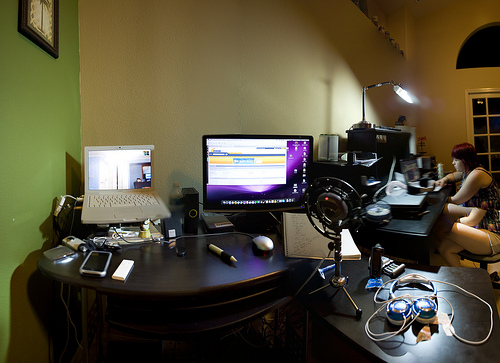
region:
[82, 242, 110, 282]
cellphone on the table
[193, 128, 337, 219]
monitor on the table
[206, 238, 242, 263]
pen on the table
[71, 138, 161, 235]
laptop on the table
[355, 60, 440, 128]
overhead light on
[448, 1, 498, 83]
half moon window over the the window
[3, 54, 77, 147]
wall is lime green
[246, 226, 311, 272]
mouse on the table in front of monitor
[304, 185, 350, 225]
red light on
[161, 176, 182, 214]
bottle in back of desk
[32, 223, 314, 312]
A large round table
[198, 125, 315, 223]
A black computer monitor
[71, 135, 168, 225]
A white laptop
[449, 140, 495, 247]
A girl sitting at desk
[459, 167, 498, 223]
A spaghetti strap top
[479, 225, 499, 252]
A pair of tan short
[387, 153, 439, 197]
A black laptop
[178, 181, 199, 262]
A black computor monitor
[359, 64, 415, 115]
A desk top lamp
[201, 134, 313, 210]
black computer screen on desk turned on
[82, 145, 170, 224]
gray laptop computer on desk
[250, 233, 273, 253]
white computer mouse on desk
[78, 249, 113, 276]
gray and black smart phone on desk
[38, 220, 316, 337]
dark wood desk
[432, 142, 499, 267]
woman with red hair on computer in background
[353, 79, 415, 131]
desk lamp turned on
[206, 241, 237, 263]
white and black pen laying on desk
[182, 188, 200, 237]
black and yellow computer speaker on desk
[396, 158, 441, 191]
black laptop computer on desk in background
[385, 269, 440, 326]
Head phones on the table.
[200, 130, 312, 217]
computer monitor on the table.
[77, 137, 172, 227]
computer laptop on the table.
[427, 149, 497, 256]
Glitch in the picture.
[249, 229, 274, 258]
Mouse on the counter.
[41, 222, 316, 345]
Round table against the wall.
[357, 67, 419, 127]
Light in the background.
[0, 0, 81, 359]
Green wall beside the table.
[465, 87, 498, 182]
Window in the background.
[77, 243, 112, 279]
Cell phone on the table.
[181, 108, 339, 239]
this is a moniter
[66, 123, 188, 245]
this is a laptop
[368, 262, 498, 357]
these are the headphones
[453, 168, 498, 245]
this is a tanktop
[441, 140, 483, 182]
this is a head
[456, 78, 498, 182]
this is a window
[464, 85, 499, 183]
these are the windows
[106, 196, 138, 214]
this is a spacebar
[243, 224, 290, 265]
this is a mouse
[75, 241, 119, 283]
this is a cellphone